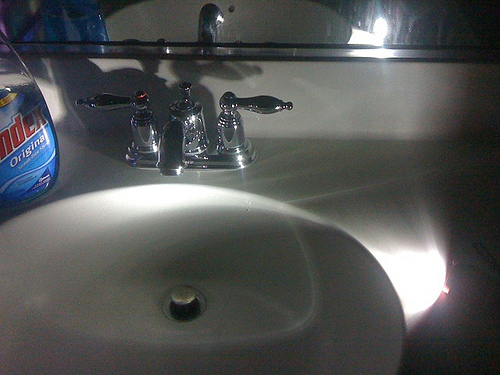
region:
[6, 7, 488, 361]
It's dark in the bathroom.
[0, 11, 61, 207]
A bottle of cleaner is on the side.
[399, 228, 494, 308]
A bright light here.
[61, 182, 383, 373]
The sink is white.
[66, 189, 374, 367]
The sink is clean.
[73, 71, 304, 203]
The faucet is glossy.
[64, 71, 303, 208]
Stainless steel fittings.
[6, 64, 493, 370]
The sink has just been cleaned.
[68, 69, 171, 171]
The top is red.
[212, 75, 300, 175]
The top is blue.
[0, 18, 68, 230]
Bottle of Windex cleaning solution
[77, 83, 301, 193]
Chrome water faucet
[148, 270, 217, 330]
Chrome drain stop in white sink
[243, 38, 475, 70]
Chrome frame on vanity mirror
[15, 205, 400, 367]
Round white sink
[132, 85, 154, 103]
Red hot water button on top of faucet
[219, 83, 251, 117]
Cold water button on top of faucet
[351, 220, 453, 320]
Light reflected on top of vanity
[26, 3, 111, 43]
Blue solution in Windex bottle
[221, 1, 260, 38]
Overflow hole in sink reflected in mirror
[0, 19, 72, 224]
bottle of Windex on sink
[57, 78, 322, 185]
metal faucets on sink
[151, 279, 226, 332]
silver stopper in sink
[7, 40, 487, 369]
white sink in a bathroom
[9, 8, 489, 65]
bottom of mirror by sink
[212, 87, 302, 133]
cold water handle on sink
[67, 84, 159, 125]
hot water handle on sink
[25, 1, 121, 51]
reflection of Windex in mirror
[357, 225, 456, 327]
light casted on the sink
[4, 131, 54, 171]
word original printed on bottle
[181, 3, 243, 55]
reflection of faucet in mirror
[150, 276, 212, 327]
drain in bottom of sink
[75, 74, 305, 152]
two metal faucet handles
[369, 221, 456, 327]
light reflection on counter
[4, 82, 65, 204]
plastic bottle of cleaner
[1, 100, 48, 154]
red word on bottle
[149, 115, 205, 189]
shiny curved faucet head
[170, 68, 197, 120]
knob to close drain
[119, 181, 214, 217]
light reflection on sink edge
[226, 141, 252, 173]
light reflection on metal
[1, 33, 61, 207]
windex original mirror cleanser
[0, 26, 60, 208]
windex cleanser on top of white sink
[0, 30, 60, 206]
bottle of windex mirror cleanser on top of bathroom's sink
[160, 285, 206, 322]
stopper to bathroom's sink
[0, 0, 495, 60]
bottom of mirror above the bathroom's sink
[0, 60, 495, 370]
white sink in the bathroom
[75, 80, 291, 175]
stainless steel faucet on top of bathroom's sink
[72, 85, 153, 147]
hot water knob on faucet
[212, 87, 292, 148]
knob to release hot water into sink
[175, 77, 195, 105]
pull up and down knob for sink's stopper